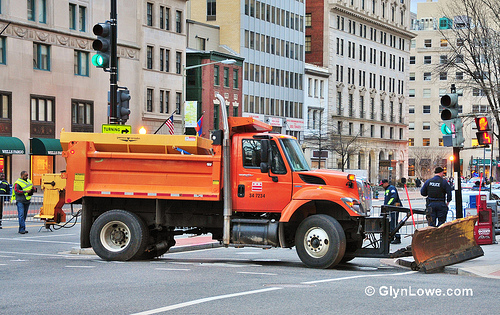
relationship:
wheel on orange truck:
[294, 213, 363, 269] [54, 110, 471, 278]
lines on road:
[114, 265, 423, 313] [3, 194, 498, 311]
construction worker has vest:
[11, 169, 39, 234] [14, 175, 36, 202]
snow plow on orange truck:
[400, 211, 487, 274] [54, 110, 471, 278]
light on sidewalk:
[439, 123, 454, 135] [399, 229, 499, 278]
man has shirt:
[420, 168, 452, 228] [417, 174, 454, 202]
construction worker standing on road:
[11, 169, 39, 234] [3, 194, 498, 311]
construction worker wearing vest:
[11, 169, 39, 234] [11, 181, 33, 201]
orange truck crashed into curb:
[54, 110, 471, 278] [394, 249, 487, 283]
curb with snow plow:
[394, 249, 487, 283] [391, 212, 487, 274]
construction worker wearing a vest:
[11, 169, 39, 234] [13, 171, 33, 210]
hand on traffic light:
[479, 117, 489, 131] [444, 95, 496, 150]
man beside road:
[420, 166, 452, 228] [399, 197, 426, 209]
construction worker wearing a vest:
[14, 167, 36, 234] [15, 176, 30, 207]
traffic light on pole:
[117, 84, 134, 121] [103, 0, 120, 127]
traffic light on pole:
[87, 17, 116, 74] [103, 0, 120, 127]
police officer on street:
[376, 176, 403, 260] [220, 258, 328, 295]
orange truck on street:
[54, 110, 471, 278] [32, 263, 136, 296]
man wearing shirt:
[420, 166, 452, 228] [425, 177, 445, 198]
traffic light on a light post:
[93, 20, 113, 68] [105, 86, 118, 127]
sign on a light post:
[128, 126, 156, 136] [105, 86, 118, 127]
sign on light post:
[89, 122, 136, 144] [91, 0, 131, 123]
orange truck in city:
[54, 110, 471, 278] [1, 3, 499, 223]